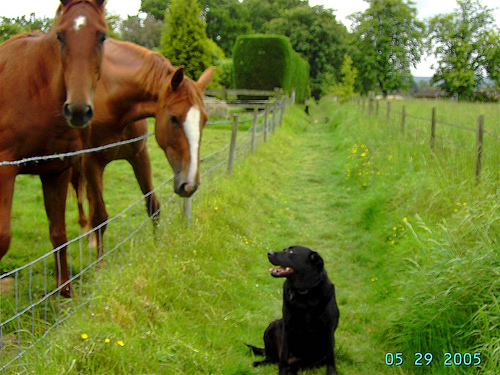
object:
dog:
[241, 244, 340, 375]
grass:
[0, 92, 499, 375]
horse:
[0, 5, 108, 297]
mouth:
[268, 259, 295, 278]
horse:
[69, 37, 216, 272]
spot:
[182, 104, 200, 193]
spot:
[72, 15, 87, 32]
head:
[52, 0, 108, 128]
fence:
[1, 96, 285, 372]